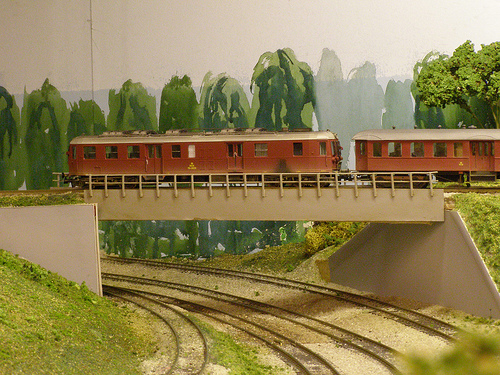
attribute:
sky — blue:
[96, 0, 498, 33]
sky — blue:
[0, 1, 500, 96]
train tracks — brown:
[106, 256, 468, 373]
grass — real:
[10, 269, 150, 356]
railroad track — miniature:
[105, 254, 465, 374]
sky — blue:
[4, 4, 498, 114]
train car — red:
[61, 126, 348, 188]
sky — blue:
[330, 6, 448, 81]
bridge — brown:
[59, 117, 494, 324]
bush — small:
[303, 222, 328, 259]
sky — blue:
[145, 30, 271, 66]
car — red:
[356, 120, 493, 192]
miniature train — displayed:
[64, 126, 494, 181]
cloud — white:
[1, 0, 496, 93]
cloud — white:
[4, 1, 498, 80]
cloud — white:
[3, 2, 498, 107]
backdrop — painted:
[3, 4, 495, 263]